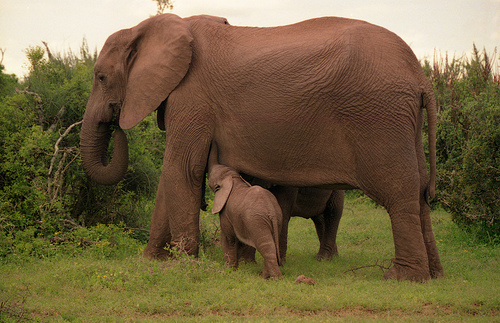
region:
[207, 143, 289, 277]
A baby elephant with his trunk up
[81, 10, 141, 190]
A curled elephant trunk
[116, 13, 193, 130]
A big elephant ear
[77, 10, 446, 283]
A mama and baby elephant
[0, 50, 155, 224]
A bunch of leafy bushes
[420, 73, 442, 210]
An elephant's hanging tail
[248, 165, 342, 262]
An elephant hiding behind his mama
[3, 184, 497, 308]
A grassy outdoor area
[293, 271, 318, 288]
A pile of elephant poop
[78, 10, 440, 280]
A large mother elephant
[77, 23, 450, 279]
two elephants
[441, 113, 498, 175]
the green bushes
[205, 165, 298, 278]
the small elephant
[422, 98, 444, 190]
the elephants tail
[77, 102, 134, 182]
the elephants trunk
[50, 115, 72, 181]
the tree branches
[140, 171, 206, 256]
the elephants front legs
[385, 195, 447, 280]
the elephants back legs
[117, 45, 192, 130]
the elephants ear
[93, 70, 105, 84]
the elephants eye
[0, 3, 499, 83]
yellow dusky sunlight sky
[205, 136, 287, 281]
small baby elephant reaching with its trunk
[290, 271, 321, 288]
brown rock in the grass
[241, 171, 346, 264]
small baby elephant behind its mother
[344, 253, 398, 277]
small broken branch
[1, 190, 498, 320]
scrubby grass patch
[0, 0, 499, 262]
stand of short trees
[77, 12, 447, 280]
large female elephant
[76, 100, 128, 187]
elephants large trunk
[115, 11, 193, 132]
large elephants ear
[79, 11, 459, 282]
an family of elephants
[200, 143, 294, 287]
a baby elephant under a mother elephant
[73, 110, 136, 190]
a trunk of an elephant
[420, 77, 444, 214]
a tail of an elephant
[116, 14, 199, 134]
an ear of an elephant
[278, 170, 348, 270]
a small elephant on the other side of a bigger elephant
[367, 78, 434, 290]
a hind leg of an elephant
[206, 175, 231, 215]
an ear of a eleaphant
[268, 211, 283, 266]
a tail of an elephant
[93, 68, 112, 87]
the eye of an elephant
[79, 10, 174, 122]
the head of an elephant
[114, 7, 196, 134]
the ear of an elephant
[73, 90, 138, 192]
the trunk of an elephant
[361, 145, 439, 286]
the leg of an elephant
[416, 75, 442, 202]
the tail of an elephant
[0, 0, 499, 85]
a gray sky overhead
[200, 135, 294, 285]
a small baby elephant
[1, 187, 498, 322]
a grassy green field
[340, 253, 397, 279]
a branch on the ground